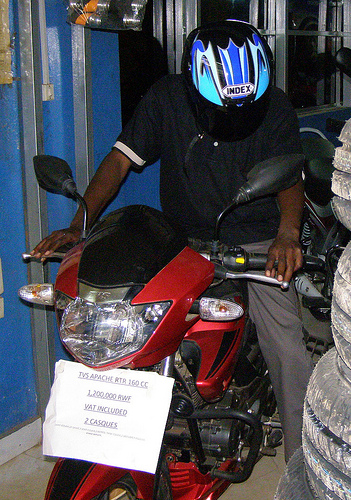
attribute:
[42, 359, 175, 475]
paper — white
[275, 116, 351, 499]
tires — piled, stacked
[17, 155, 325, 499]
motorcycle — black, red, parked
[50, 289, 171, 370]
headlight — off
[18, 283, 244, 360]
lights — off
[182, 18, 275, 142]
helmet — black, blue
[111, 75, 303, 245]
shirt — short sleeved, black, white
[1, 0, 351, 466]
wall — blue, grey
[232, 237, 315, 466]
pants — grey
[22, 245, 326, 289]
handlebars — metal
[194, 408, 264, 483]
foot hold — black